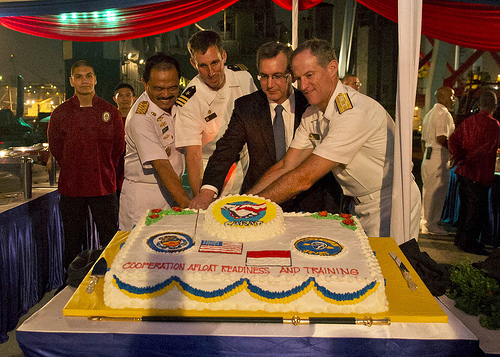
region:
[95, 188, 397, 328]
large iced cake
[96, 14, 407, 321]
military members in front of a large iced cake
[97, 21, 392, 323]
four men cutting a large cake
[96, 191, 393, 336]
large white cake with lettering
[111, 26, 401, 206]
three men in military uniforms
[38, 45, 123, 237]
waitstaff standing in dark red jacket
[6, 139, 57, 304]
banquet area dressed with dark blue cloth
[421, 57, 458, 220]
profile of a black man in a white uniform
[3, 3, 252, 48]
red sash hanging from a ceiling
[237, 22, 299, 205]
man with dark suit and blue tie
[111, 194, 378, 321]
this is a cake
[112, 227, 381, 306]
the cake is rectangular in shape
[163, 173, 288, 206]
the men are cutting the cake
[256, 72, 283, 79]
this is a spectacle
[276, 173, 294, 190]
the man has light skin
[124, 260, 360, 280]
this is a writing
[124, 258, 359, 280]
the writing is in red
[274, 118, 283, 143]
this is a neck tie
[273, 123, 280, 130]
the neck tie is black in color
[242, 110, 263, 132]
this is a black coat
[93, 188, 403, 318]
Large rectangular cake.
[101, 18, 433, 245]
Four men cutting the cake.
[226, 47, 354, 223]
Man in a suit and tie.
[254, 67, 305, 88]
Glasses on the man in a suit's face.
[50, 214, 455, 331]
Large yellow serving platter under the cake.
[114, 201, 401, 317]
Primarily white frosting on the cake.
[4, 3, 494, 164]
Photo taken in the evening.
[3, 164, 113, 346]
Blue table cloth.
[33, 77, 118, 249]
Food service worker.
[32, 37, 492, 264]
Nine total people in the photo.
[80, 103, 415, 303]
four men cutting a cake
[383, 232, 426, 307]
silver knife to cut cake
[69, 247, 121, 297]
silver cake server on table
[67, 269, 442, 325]
cake is on yellow platform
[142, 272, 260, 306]
cake is trimmed in blue and yellow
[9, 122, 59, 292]
buffet table with hot foods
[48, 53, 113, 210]
man with red jacket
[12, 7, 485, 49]
decorations include a red cloth swag overhead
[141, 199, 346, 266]
special emblems on cake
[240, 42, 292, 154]
man in brown suit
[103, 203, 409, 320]
a large decorated cake on a yellow base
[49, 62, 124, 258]
an Asian waiter standing in the background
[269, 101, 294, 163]
a blue tie a man with glasses is wearng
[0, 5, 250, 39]
a red and blue swag of fabric hanging from the ceiling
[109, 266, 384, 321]
blue and yellow decoration on the side of the cake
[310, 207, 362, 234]
red flowers in icing on the cake as decoration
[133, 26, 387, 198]
three officers and a business man getting ready to cut the cake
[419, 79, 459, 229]
a man in a white uniform in the background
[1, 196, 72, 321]
a blue fabric skirt on the nearby table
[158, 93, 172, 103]
a black mustache a man is wearing